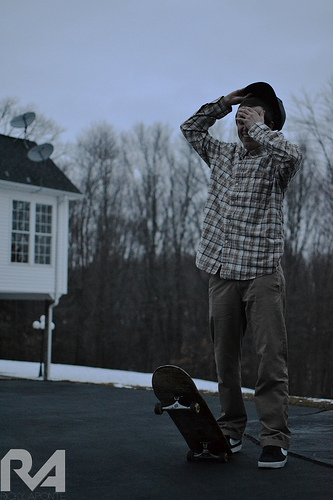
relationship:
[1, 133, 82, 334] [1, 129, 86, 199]
house with roof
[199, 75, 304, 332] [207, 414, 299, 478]
boy wearing shoes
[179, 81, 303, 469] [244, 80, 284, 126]
boy touching cap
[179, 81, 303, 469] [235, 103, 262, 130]
boy touching with right hand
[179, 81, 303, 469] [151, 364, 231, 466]
boy holds skateboard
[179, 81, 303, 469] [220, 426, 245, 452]
boy holds with foot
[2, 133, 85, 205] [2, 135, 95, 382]
roof of house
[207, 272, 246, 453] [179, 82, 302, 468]
leg of man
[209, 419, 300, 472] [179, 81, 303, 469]
feet of boy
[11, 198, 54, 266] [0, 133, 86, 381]
window on corner of house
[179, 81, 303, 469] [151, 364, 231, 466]
boy standing on skateboard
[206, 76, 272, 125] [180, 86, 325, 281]
hands on boy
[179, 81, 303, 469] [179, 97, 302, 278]
boy wearing shirt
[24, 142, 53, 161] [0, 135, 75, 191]
discs on roof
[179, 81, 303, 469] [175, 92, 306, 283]
boy wears shirt